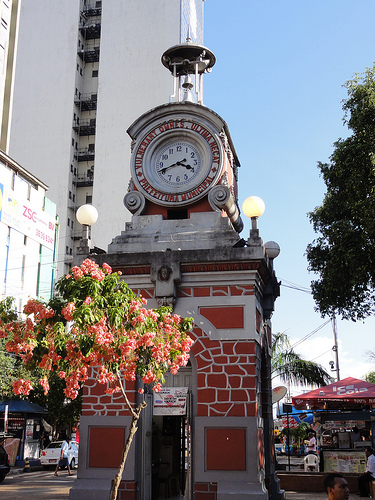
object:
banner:
[152, 386, 188, 416]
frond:
[272, 327, 337, 388]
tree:
[271, 326, 338, 388]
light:
[242, 195, 266, 220]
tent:
[292, 376, 375, 409]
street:
[0, 438, 372, 500]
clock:
[141, 126, 212, 196]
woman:
[53, 433, 74, 477]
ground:
[0, 460, 76, 500]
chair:
[304, 454, 320, 473]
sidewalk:
[276, 455, 323, 473]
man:
[53, 432, 72, 481]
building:
[0, 0, 280, 500]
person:
[303, 432, 316, 457]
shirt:
[308, 437, 317, 453]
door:
[142, 381, 198, 500]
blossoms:
[0, 257, 193, 402]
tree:
[0, 258, 212, 500]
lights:
[75, 204, 99, 227]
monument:
[67, 0, 282, 500]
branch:
[14, 287, 159, 369]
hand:
[176, 160, 195, 169]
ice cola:
[333, 383, 369, 396]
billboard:
[0, 183, 57, 253]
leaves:
[300, 60, 375, 324]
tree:
[300, 56, 375, 326]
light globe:
[75, 204, 98, 226]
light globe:
[243, 194, 265, 219]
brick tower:
[66, 0, 286, 500]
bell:
[182, 74, 194, 90]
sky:
[198, 1, 375, 415]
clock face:
[155, 138, 203, 186]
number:
[185, 146, 188, 153]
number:
[191, 151, 196, 158]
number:
[193, 159, 198, 166]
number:
[190, 166, 195, 173]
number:
[176, 175, 181, 182]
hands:
[157, 157, 187, 173]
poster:
[152, 386, 188, 416]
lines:
[7, 476, 79, 485]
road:
[0, 458, 78, 500]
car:
[40, 441, 70, 471]